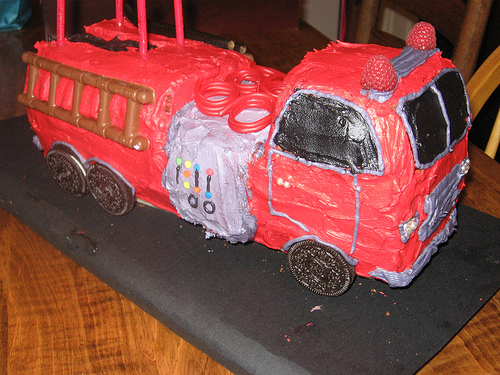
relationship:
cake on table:
[18, 6, 480, 301] [1, 2, 499, 374]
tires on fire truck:
[26, 144, 363, 303] [16, 18, 470, 298]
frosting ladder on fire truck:
[15, 47, 153, 154] [16, 18, 470, 298]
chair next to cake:
[466, 47, 498, 157] [18, 6, 480, 301]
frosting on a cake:
[22, 0, 469, 288] [18, 6, 480, 301]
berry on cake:
[362, 55, 399, 100] [18, 6, 480, 301]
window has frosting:
[283, 96, 388, 172] [266, 90, 385, 173]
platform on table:
[1, 115, 499, 368] [1, 2, 499, 374]